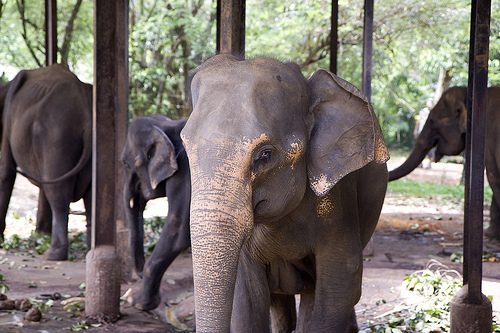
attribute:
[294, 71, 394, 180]
ear — big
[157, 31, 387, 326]
elephant — here, huge, standing, walking, shaded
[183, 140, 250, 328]
trunk — here, long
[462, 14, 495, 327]
post — here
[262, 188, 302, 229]
jaw — here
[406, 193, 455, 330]
ground — here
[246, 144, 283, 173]
eye — here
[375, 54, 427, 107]
plant — here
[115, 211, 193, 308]
leg — here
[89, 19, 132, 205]
metal — here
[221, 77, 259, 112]
fur — grey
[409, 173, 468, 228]
grass — here, green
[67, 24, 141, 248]
pillar — here, metal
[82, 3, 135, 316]
pole — here, metal, wooden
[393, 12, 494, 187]
tree — here, green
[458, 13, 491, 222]
beam — metal